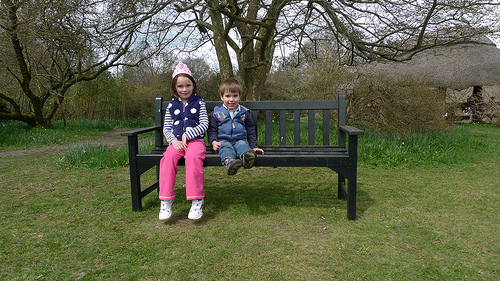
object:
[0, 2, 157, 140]
tree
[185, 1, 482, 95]
tree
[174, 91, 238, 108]
smiles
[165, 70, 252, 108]
faces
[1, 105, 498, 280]
grass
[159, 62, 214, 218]
child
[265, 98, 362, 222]
bench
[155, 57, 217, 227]
girl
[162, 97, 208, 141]
shirt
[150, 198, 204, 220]
shoes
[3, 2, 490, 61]
tree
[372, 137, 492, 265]
grass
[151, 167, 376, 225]
shadow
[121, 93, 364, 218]
bench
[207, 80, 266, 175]
boy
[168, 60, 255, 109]
head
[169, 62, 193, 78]
tiara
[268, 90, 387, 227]
bench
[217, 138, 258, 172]
jeans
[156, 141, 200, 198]
trousers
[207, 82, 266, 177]
boy dressed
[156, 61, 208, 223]
girl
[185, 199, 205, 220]
sneaker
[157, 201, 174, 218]
sneaker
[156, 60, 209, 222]
child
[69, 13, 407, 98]
tree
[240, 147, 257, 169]
shoe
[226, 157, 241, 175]
shoe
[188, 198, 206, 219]
shoe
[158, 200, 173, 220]
shoe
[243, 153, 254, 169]
shoe bottom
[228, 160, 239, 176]
shoe bottom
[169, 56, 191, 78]
tiara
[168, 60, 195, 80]
hat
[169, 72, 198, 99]
head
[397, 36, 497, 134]
building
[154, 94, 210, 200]
pants shirt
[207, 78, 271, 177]
boy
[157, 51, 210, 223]
girl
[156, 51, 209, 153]
girl's hand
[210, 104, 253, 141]
shirt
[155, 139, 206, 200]
pants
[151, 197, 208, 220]
feet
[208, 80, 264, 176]
child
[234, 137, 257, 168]
leg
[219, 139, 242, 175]
leg